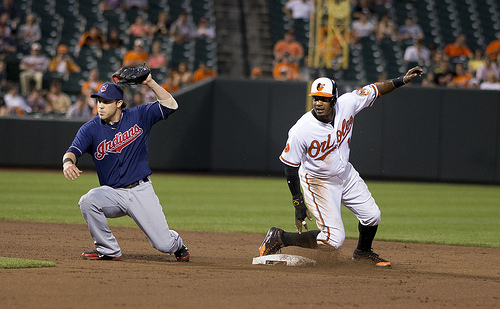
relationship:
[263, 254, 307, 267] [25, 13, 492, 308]
base in baseball game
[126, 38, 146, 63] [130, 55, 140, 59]
person wearing shirt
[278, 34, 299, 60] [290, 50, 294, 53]
person wearing shirt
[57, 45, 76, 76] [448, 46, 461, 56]
person wearing shirt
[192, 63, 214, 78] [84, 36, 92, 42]
person wearing shirt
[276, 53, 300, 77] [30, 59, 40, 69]
person wearing shirt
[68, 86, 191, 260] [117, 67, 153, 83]
person with baseball glove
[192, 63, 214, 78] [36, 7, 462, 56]
person in stand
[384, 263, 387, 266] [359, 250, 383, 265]
tip of shoe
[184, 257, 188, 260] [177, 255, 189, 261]
tip of shoe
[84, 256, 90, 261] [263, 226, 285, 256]
tip of shoe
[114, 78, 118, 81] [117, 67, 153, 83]
marking on baseball glove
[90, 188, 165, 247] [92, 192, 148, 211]
man wearing pants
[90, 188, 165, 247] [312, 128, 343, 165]
man wearing shirt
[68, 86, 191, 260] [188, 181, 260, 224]
player on field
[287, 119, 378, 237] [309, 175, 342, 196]
person wearing uniform